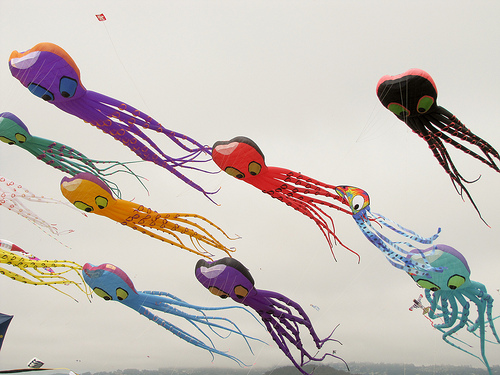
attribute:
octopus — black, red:
[372, 66, 499, 233]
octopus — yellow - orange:
[54, 168, 239, 273]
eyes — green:
[73, 193, 108, 213]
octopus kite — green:
[3, 108, 150, 205]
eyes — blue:
[25, 75, 81, 102]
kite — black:
[345, 60, 486, 175]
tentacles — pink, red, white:
[7, 182, 63, 241]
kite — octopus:
[0, 168, 67, 241]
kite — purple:
[184, 114, 393, 274]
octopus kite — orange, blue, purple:
[3, 36, 228, 211]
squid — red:
[208, 137, 365, 264]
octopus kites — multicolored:
[3, 29, 490, 371]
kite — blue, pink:
[77, 253, 279, 368]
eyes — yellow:
[93, 187, 123, 220]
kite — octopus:
[67, 159, 232, 250]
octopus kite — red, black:
[220, 125, 361, 247]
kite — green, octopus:
[1, 115, 161, 202]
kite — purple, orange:
[9, 42, 222, 202]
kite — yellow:
[377, 67, 499, 219]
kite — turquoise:
[403, 237, 493, 373]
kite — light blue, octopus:
[6, 43, 167, 113]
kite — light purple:
[374, 68, 471, 180]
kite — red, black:
[188, 134, 379, 261]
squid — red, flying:
[207, 133, 389, 264]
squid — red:
[156, 130, 354, 277]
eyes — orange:
[222, 161, 265, 179]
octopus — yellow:
[5, 240, 88, 306]